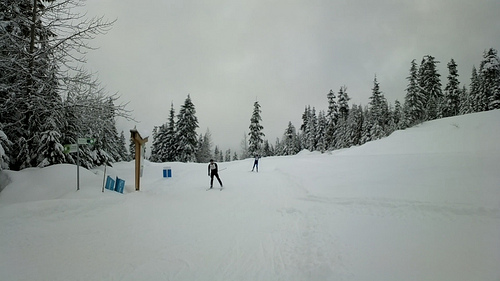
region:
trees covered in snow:
[257, 36, 494, 163]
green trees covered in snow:
[291, 31, 495, 170]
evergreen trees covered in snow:
[289, 28, 494, 156]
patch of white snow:
[253, 157, 480, 255]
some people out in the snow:
[183, 143, 305, 224]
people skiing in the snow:
[184, 128, 290, 211]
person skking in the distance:
[194, 150, 224, 207]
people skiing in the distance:
[202, 141, 274, 202]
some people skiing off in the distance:
[194, 142, 275, 212]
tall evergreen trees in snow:
[0, 0, 114, 161]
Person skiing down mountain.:
[199, 157, 238, 226]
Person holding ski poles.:
[200, 160, 229, 182]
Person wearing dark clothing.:
[208, 157, 243, 217]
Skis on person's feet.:
[198, 187, 236, 195]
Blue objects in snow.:
[103, 164, 130, 194]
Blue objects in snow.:
[161, 158, 186, 196]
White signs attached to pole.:
[51, 130, 123, 184]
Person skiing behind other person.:
[248, 145, 291, 220]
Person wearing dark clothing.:
[250, 155, 263, 177]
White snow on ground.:
[181, 183, 273, 275]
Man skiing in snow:
[199, 157, 229, 189]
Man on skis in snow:
[199, 156, 230, 194]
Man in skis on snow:
[202, 153, 225, 192]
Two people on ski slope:
[193, 147, 268, 189]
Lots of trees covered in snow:
[292, 76, 403, 149]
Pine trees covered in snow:
[148, 98, 207, 161]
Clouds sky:
[97, 43, 401, 115]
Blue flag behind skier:
[162, 166, 172, 178]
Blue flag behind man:
[158, 164, 178, 181]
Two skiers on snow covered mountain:
[199, 142, 271, 192]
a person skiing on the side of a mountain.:
[193, 156, 232, 194]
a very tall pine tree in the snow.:
[240, 91, 268, 158]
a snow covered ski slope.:
[3, 106, 495, 278]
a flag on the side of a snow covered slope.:
[159, 167, 176, 183]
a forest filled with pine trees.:
[3, 0, 497, 172]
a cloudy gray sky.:
[20, 1, 497, 158]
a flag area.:
[97, 162, 129, 205]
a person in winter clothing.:
[188, 148, 228, 196]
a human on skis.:
[249, 136, 277, 178]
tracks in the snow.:
[258, 164, 399, 247]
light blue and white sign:
[106, 176, 116, 191]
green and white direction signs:
[59, 133, 97, 191]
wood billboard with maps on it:
[133, 124, 150, 195]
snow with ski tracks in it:
[276, 175, 498, 278]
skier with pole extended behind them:
[205, 156, 230, 195]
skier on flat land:
[249, 149, 262, 173]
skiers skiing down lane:
[206, 147, 266, 192]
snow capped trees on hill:
[287, 43, 498, 137]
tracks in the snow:
[243, 229, 308, 279]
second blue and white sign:
[114, 176, 125, 194]